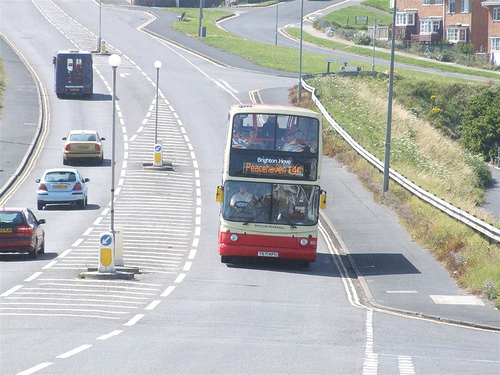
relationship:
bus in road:
[218, 106, 325, 267] [1, 1, 374, 372]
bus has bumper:
[218, 106, 325, 267] [223, 231, 317, 261]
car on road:
[33, 165, 90, 208] [1, 1, 374, 372]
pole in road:
[105, 55, 125, 269] [1, 1, 374, 372]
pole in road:
[148, 63, 169, 174] [1, 1, 374, 372]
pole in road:
[95, 3, 107, 54] [1, 1, 374, 372]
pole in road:
[384, 4, 395, 194] [1, 1, 374, 372]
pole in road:
[294, 3, 305, 97] [1, 1, 374, 372]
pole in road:
[272, 3, 281, 52] [1, 1, 374, 372]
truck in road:
[52, 52, 92, 98] [1, 1, 374, 372]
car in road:
[33, 165, 90, 208] [1, 1, 374, 372]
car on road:
[38, 169, 87, 204] [1, 1, 374, 372]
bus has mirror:
[218, 106, 325, 267] [215, 183, 222, 203]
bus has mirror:
[218, 106, 325, 267] [317, 188, 326, 210]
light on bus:
[230, 233, 237, 242] [218, 106, 325, 267]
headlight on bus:
[298, 235, 311, 249] [218, 106, 325, 267]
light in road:
[111, 54, 121, 66] [1, 1, 374, 372]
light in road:
[153, 57, 161, 68] [1, 1, 374, 372]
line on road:
[352, 306, 383, 374] [1, 1, 374, 372]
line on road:
[126, 78, 161, 149] [1, 1, 374, 372]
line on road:
[168, 39, 256, 118] [1, 1, 374, 372]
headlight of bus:
[298, 235, 307, 248] [218, 106, 325, 267]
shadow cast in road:
[325, 247, 417, 282] [148, 272, 459, 359]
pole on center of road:
[97, 50, 132, 265] [27, 153, 232, 373]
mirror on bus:
[317, 188, 330, 212] [201, 100, 325, 270]